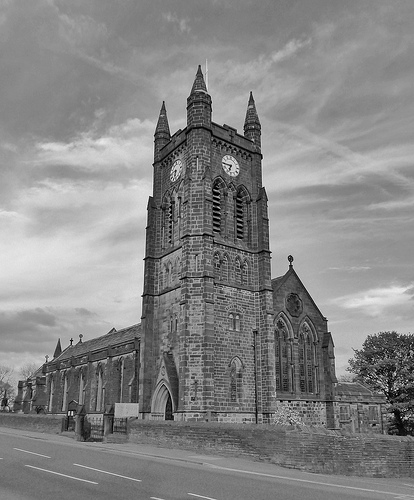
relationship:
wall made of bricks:
[210, 125, 259, 422] [210, 140, 261, 420]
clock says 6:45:
[219, 152, 241, 179] [223, 160, 233, 173]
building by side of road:
[16, 64, 384, 446] [1, 427, 413, 498]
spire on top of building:
[188, 65, 212, 122] [16, 64, 384, 446]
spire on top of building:
[245, 91, 263, 145] [16, 64, 384, 446]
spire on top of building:
[152, 99, 168, 157] [16, 64, 384, 446]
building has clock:
[16, 64, 384, 446] [219, 152, 241, 179]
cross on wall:
[226, 132, 235, 144] [210, 125, 259, 422]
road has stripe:
[1, 427, 413, 498] [74, 461, 143, 484]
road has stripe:
[1, 427, 413, 498] [25, 462, 99, 492]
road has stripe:
[1, 427, 413, 498] [12, 445, 54, 461]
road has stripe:
[1, 427, 413, 498] [185, 490, 223, 499]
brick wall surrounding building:
[0, 414, 413, 477] [16, 64, 384, 446]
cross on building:
[226, 132, 235, 144] [16, 64, 384, 446]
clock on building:
[219, 152, 241, 179] [16, 64, 384, 446]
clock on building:
[169, 160, 185, 181] [16, 64, 384, 446]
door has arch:
[160, 393, 176, 419] [147, 351, 174, 384]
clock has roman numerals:
[219, 152, 241, 179] [225, 157, 230, 162]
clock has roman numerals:
[169, 160, 185, 181] [177, 164, 183, 169]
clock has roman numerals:
[219, 152, 241, 179] [234, 171, 239, 175]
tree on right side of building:
[345, 331, 413, 435] [16, 64, 384, 446]